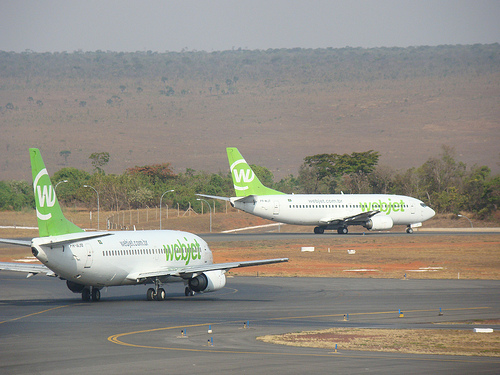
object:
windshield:
[418, 202, 426, 208]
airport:
[0, 0, 499, 374]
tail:
[27, 147, 84, 237]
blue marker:
[436, 305, 443, 317]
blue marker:
[397, 306, 404, 318]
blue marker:
[333, 342, 339, 351]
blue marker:
[240, 316, 250, 329]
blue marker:
[206, 335, 214, 346]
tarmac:
[0, 271, 499, 374]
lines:
[107, 306, 499, 362]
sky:
[0, 0, 499, 54]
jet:
[187, 271, 206, 291]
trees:
[0, 178, 36, 213]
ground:
[0, 267, 499, 373]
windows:
[397, 203, 413, 209]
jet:
[361, 220, 372, 230]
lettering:
[359, 197, 408, 215]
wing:
[326, 209, 382, 225]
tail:
[226, 147, 284, 197]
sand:
[0, 209, 499, 281]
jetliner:
[193, 147, 436, 234]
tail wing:
[195, 192, 230, 201]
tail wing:
[0, 238, 32, 246]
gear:
[154, 287, 166, 301]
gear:
[91, 287, 100, 301]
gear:
[337, 223, 348, 235]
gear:
[312, 225, 326, 234]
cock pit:
[417, 200, 432, 208]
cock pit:
[203, 240, 212, 251]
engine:
[187, 268, 226, 293]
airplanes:
[0, 147, 290, 302]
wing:
[135, 256, 289, 283]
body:
[82, 228, 203, 285]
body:
[260, 193, 408, 227]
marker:
[179, 328, 187, 336]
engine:
[360, 216, 394, 231]